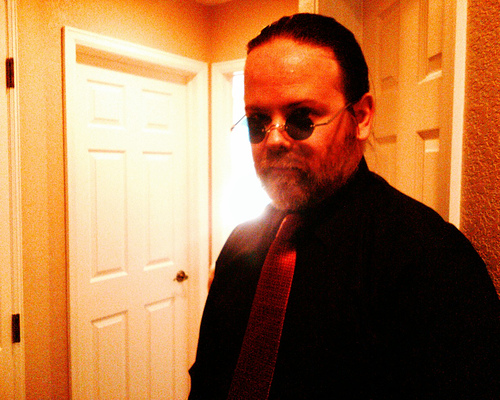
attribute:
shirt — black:
[187, 154, 499, 399]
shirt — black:
[178, 191, 498, 394]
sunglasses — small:
[231, 112, 358, 142]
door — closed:
[351, 1, 456, 237]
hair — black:
[237, 6, 375, 109]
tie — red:
[227, 195, 337, 397]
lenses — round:
[284, 110, 315, 140]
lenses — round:
[245, 114, 265, 144]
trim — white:
[5, 3, 42, 398]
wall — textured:
[447, 1, 497, 284]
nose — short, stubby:
[264, 113, 294, 153]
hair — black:
[249, 5, 371, 95]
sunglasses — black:
[228, 101, 357, 144]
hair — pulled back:
[230, 0, 389, 99]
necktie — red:
[228, 210, 306, 398]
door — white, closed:
[61, 30, 209, 398]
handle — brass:
[172, 269, 188, 282]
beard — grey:
[249, 119, 364, 216]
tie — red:
[218, 214, 303, 399]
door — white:
[21, 43, 228, 355]